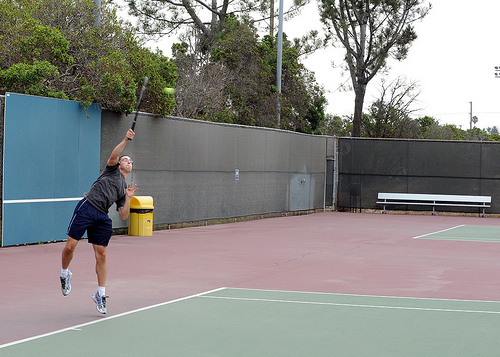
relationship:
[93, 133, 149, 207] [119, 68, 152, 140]
man holding racket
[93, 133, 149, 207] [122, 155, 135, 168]
man wearing eyeglasses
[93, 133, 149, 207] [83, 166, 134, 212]
man wearing tshirt